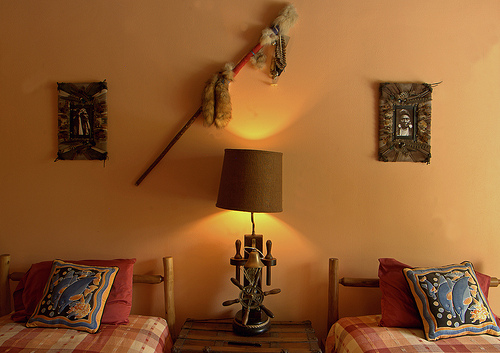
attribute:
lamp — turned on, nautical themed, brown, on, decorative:
[214, 144, 294, 339]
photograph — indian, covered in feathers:
[53, 76, 109, 168]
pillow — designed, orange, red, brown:
[21, 251, 122, 337]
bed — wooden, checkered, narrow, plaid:
[3, 246, 177, 353]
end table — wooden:
[169, 308, 322, 353]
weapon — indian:
[125, 3, 302, 190]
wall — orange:
[0, 2, 498, 322]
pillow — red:
[8, 255, 140, 331]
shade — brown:
[207, 144, 289, 220]